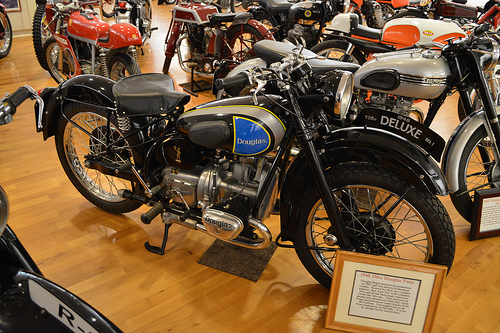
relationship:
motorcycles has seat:
[32, 45, 459, 298] [98, 70, 190, 112]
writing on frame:
[372, 281, 406, 314] [322, 229, 453, 330]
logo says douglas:
[236, 110, 280, 166] [238, 134, 270, 145]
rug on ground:
[205, 237, 287, 275] [56, 195, 369, 301]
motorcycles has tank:
[32, 45, 459, 298] [157, 165, 213, 210]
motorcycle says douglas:
[42, 17, 150, 53] [238, 134, 270, 145]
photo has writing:
[309, 240, 469, 332] [372, 281, 406, 314]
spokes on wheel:
[86, 132, 122, 171] [64, 99, 147, 225]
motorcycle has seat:
[42, 17, 150, 53] [98, 70, 190, 112]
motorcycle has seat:
[243, 32, 498, 159] [258, 24, 351, 74]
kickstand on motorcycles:
[144, 218, 182, 263] [32, 45, 459, 298]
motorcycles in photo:
[51, 24, 465, 203] [309, 240, 469, 332]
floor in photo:
[29, 228, 279, 331] [309, 240, 469, 332]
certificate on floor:
[477, 182, 498, 230] [29, 228, 279, 331]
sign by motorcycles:
[322, 229, 453, 330] [32, 45, 459, 298]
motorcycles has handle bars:
[32, 45, 459, 298] [206, 63, 302, 83]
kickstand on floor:
[144, 218, 182, 263] [29, 228, 279, 331]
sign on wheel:
[358, 105, 441, 152] [309, 162, 455, 266]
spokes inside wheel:
[86, 132, 122, 171] [64, 99, 147, 225]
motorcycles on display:
[51, 24, 465, 203] [19, 20, 498, 193]